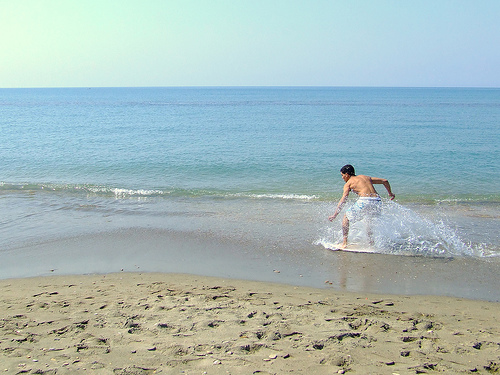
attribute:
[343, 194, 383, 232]
shorts — white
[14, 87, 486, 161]
ocean — blue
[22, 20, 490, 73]
sky — blue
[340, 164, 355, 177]
hair — black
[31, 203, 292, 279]
sand — wet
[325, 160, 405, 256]
man — young, surfing, bending forward, boogie boarder